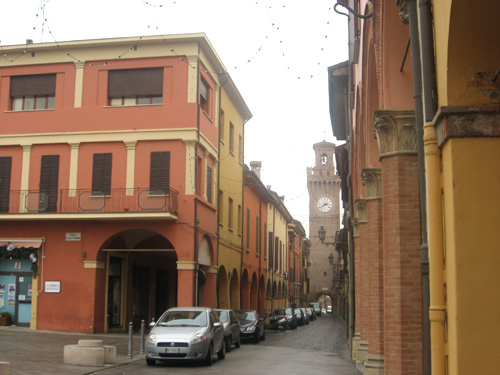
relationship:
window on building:
[88, 51, 194, 115] [0, 28, 252, 337]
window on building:
[19, 77, 56, 107] [0, 28, 252, 337]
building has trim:
[0, 37, 311, 315] [2, 33, 222, 224]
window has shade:
[7, 77, 55, 112] [13, 76, 53, 95]